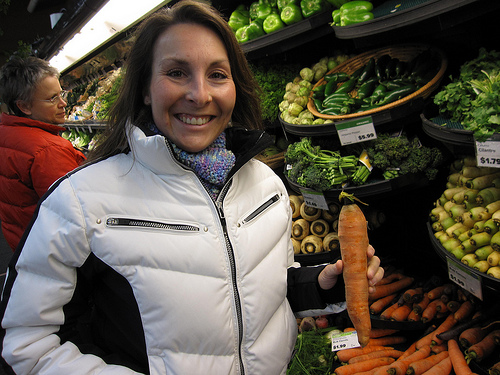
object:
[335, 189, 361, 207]
top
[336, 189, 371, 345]
carrot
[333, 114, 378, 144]
sign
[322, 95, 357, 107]
pepper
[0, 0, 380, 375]
woman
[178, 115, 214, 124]
teeth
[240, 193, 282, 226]
zipper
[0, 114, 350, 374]
jacket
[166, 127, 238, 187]
scarf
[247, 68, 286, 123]
lettuce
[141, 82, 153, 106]
ear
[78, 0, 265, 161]
hair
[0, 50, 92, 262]
lady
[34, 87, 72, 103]
glasses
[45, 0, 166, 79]
light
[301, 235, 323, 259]
turnip